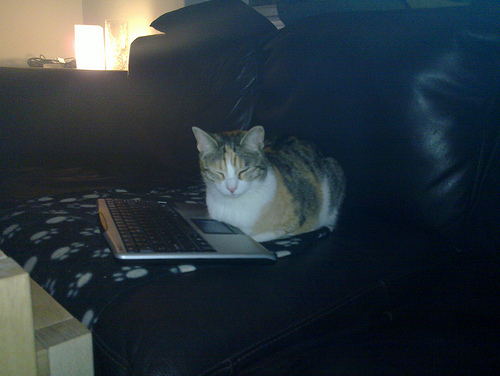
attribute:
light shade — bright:
[68, 14, 126, 67]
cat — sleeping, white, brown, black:
[186, 121, 348, 240]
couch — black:
[1, 2, 498, 371]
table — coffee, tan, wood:
[0, 245, 96, 375]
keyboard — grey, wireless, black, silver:
[116, 200, 195, 250]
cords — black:
[24, 53, 72, 68]